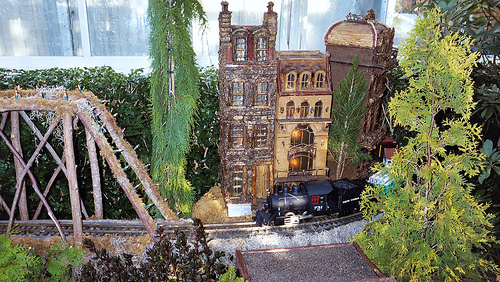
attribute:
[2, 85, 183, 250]
structure — over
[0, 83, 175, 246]
bridge — wooden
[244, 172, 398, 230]
train — green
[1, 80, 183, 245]
overhang — wooden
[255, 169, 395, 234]
engine — black, steam engine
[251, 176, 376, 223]
train — model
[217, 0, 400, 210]
mansion — old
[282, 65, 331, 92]
windows — rowed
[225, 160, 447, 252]
train — Model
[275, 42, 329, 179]
building — tall, brown, tan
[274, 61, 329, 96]
windows — arched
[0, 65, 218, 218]
green bushes — fake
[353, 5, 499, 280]
tree — bright green, model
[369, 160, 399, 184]
pipes — white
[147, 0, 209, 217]
tree — green, very tall, evergreen